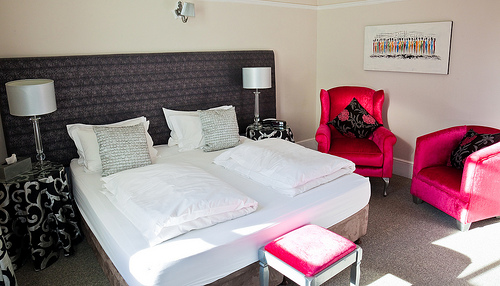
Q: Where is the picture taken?
A: Bedroom.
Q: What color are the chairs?
A: Red.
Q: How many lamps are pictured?
A: 3.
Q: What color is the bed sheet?
A: White.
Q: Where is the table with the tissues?
A: On the left.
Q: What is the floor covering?
A: Carpet.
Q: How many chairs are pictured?
A: 2.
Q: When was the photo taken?
A: Daytime.